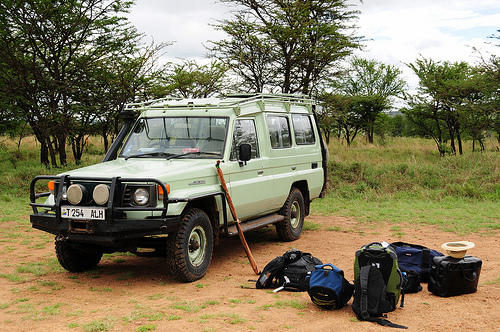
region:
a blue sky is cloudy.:
[376, 10, 466, 54]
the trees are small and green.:
[331, 32, 498, 155]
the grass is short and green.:
[376, 160, 486, 211]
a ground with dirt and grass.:
[38, 284, 199, 326]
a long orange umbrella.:
[211, 156, 263, 275]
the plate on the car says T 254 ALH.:
[58, 197, 110, 228]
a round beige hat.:
[436, 229, 478, 263]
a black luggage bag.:
[425, 253, 486, 298]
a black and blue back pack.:
[301, 257, 352, 309]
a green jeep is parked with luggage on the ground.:
[17, 85, 490, 329]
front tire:
[171, 223, 214, 275]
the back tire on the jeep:
[280, 203, 312, 238]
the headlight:
[131, 185, 148, 205]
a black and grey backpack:
[353, 267, 381, 314]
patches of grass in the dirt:
[17, 298, 101, 328]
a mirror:
[236, 145, 253, 161]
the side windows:
[267, 115, 314, 142]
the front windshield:
[132, 120, 216, 152]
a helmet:
[436, 237, 473, 256]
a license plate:
[60, 205, 107, 221]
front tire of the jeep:
[180, 220, 222, 274]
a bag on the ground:
[302, 255, 349, 307]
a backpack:
[354, 273, 386, 319]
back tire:
[285, 191, 310, 235]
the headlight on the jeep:
[130, 189, 155, 206]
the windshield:
[134, 113, 227, 162]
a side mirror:
[239, 144, 253, 161]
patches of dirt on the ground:
[130, 311, 182, 325]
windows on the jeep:
[266, 116, 321, 149]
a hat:
[436, 238, 475, 256]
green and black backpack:
[349, 239, 405, 322]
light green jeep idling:
[26, 88, 328, 283]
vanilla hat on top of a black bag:
[440, 238, 475, 261]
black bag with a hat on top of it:
[423, 253, 485, 299]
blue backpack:
[302, 259, 357, 309]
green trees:
[336, 59, 495, 156]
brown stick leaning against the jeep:
[210, 159, 264, 279]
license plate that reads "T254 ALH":
[57, 207, 109, 219]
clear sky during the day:
[140, 1, 498, 66]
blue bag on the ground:
[381, 239, 443, 280]